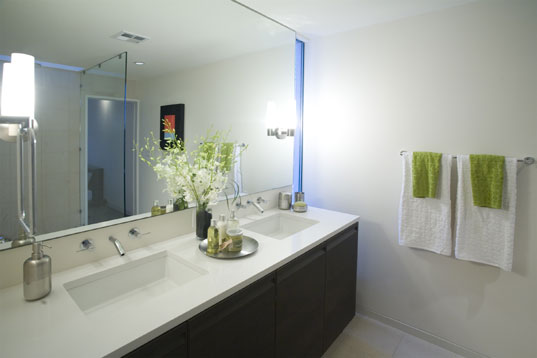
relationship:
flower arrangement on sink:
[134, 132, 226, 244] [57, 246, 210, 315]